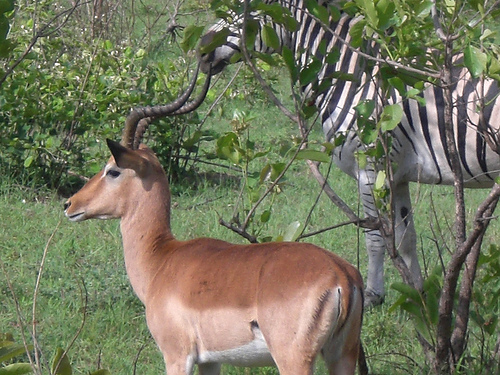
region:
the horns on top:
[116, 57, 216, 150]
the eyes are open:
[101, 167, 123, 179]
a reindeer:
[63, 55, 369, 370]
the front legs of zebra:
[351, 158, 427, 311]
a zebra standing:
[191, 4, 497, 306]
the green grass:
[1, 88, 498, 370]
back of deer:
[316, 264, 372, 364]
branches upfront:
[3, 169, 495, 374]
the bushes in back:
[6, 2, 499, 178]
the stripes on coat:
[253, 14, 499, 179]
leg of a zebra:
[353, 179, 399, 296]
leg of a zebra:
[380, 168, 454, 285]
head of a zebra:
[188, 4, 305, 68]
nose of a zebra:
[183, 25, 226, 64]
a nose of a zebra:
[185, 40, 216, 58]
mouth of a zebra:
[195, 58, 223, 79]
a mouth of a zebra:
[203, 52, 262, 75]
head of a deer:
[43, 120, 179, 237]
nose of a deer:
[53, 194, 81, 215]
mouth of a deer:
[56, 205, 91, 227]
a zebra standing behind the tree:
[192, 4, 499, 306]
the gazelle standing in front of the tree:
[60, 59, 369, 374]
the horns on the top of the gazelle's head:
[116, 60, 212, 145]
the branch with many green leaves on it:
[203, 0, 498, 167]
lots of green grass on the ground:
[8, 193, 499, 369]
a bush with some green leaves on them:
[2, 10, 221, 189]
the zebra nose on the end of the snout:
[189, 34, 209, 62]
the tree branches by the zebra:
[306, 160, 495, 368]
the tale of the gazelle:
[331, 286, 354, 342]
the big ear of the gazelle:
[101, 131, 146, 183]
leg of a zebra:
[335, 190, 411, 316]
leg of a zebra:
[388, 207, 445, 290]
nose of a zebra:
[192, 34, 219, 55]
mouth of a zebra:
[196, 55, 240, 89]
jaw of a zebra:
[176, 18, 262, 75]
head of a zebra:
[199, 7, 356, 85]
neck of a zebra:
[283, 15, 398, 127]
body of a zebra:
[365, 27, 487, 210]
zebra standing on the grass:
[193, 0, 495, 310]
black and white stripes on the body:
[196, 3, 498, 313]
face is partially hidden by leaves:
[178, 0, 330, 81]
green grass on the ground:
[4, 0, 494, 373]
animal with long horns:
[51, 58, 392, 373]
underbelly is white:
[199, 333, 281, 370]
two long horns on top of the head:
[111, 66, 235, 153]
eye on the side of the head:
[103, 168, 127, 179]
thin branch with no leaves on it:
[30, 216, 57, 359]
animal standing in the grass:
[44, 59, 378, 373]